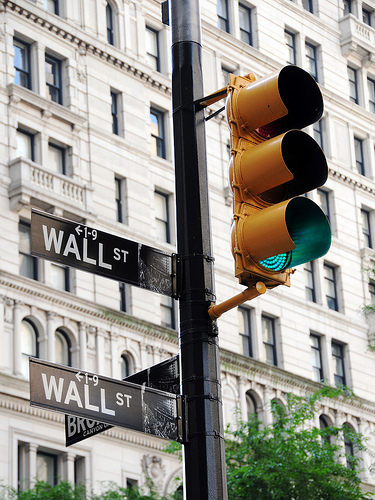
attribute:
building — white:
[1, 0, 373, 497]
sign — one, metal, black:
[33, 210, 174, 293]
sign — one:
[30, 360, 175, 435]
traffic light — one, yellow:
[195, 66, 330, 317]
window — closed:
[14, 30, 31, 90]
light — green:
[255, 213, 290, 274]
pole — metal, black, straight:
[169, 0, 227, 499]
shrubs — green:
[4, 386, 375, 500]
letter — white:
[97, 241, 114, 270]